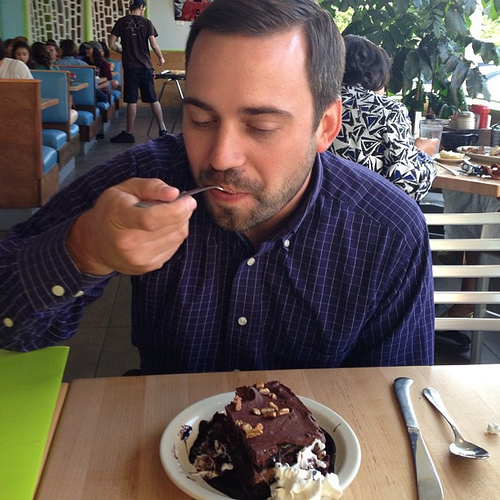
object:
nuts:
[252, 401, 291, 419]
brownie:
[218, 375, 326, 463]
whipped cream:
[289, 469, 329, 485]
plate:
[158, 393, 201, 485]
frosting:
[224, 434, 273, 461]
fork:
[188, 184, 240, 206]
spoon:
[422, 367, 492, 470]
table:
[56, 388, 127, 470]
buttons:
[235, 256, 264, 268]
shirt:
[149, 262, 397, 349]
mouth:
[188, 169, 256, 210]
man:
[40, 0, 430, 355]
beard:
[207, 220, 271, 229]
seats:
[19, 131, 82, 157]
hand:
[79, 166, 167, 298]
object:
[1, 382, 84, 420]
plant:
[389, 4, 460, 90]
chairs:
[96, 93, 113, 111]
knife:
[386, 369, 448, 497]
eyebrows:
[180, 89, 288, 121]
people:
[1, 20, 131, 107]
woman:
[336, 24, 420, 177]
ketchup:
[468, 92, 492, 126]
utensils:
[396, 376, 484, 490]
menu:
[1, 393, 36, 442]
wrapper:
[438, 156, 463, 175]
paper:
[419, 140, 448, 175]